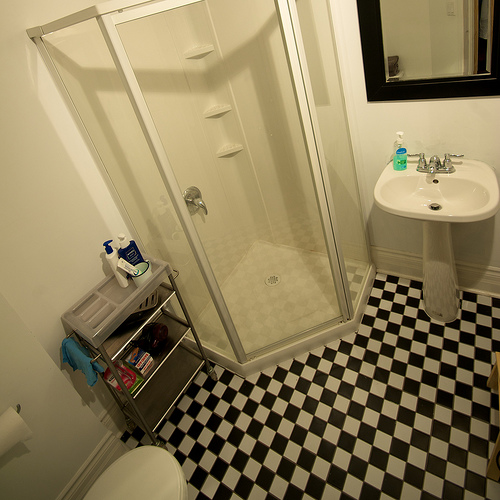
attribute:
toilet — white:
[83, 444, 188, 497]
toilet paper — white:
[2, 408, 33, 459]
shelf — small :
[216, 140, 243, 159]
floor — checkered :
[226, 329, 467, 499]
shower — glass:
[25, 2, 377, 376]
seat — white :
[79, 442, 186, 498]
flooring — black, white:
[261, 366, 426, 494]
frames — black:
[355, 0, 496, 104]